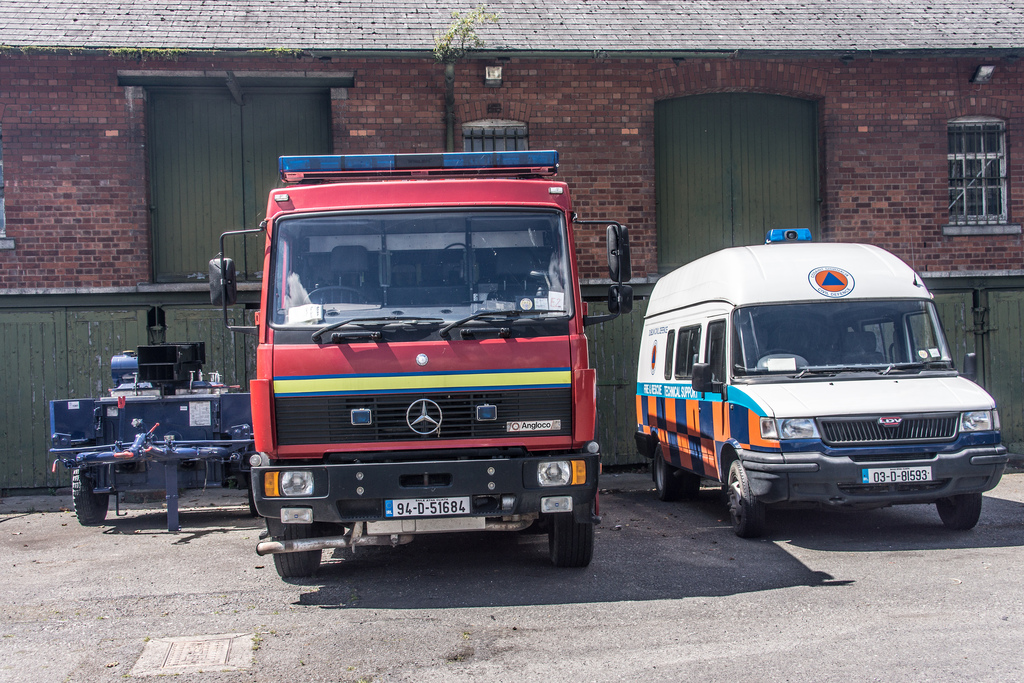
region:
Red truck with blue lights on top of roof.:
[191, 142, 635, 585]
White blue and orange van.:
[626, 222, 1006, 529]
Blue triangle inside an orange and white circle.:
[806, 259, 857, 299]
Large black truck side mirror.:
[201, 249, 243, 311]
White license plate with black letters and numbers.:
[380, 493, 475, 525]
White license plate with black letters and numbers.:
[855, 462, 935, 488]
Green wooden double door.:
[137, 76, 338, 293]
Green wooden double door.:
[650, 89, 827, 280]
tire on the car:
[267, 552, 313, 576]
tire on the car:
[550, 522, 612, 571]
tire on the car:
[933, 470, 975, 532]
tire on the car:
[640, 451, 676, 493]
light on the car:
[288, 464, 328, 513]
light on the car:
[525, 448, 579, 494]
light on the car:
[770, 418, 822, 442]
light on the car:
[551, 458, 574, 526]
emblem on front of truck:
[397, 390, 447, 442]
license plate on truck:
[376, 488, 487, 524]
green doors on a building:
[626, 74, 878, 274]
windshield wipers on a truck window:
[311, 296, 559, 353]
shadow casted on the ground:
[605, 463, 702, 609]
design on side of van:
[632, 373, 768, 491]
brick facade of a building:
[849, 73, 926, 239]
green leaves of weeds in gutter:
[429, 8, 503, 58]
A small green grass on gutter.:
[430, 12, 501, 66]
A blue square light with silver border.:
[348, 407, 374, 426]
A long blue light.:
[275, 149, 561, 169]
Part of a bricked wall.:
[849, 162, 929, 238]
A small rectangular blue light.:
[768, 227, 814, 244]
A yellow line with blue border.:
[269, 363, 579, 399]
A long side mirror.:
[604, 221, 631, 280]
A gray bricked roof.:
[0, 0, 1022, 49]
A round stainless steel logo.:
[403, 396, 446, 435]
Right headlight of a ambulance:
[952, 405, 1001, 438]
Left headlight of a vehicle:
[253, 463, 321, 508]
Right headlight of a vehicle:
[523, 452, 590, 495]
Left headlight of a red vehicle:
[256, 465, 318, 504]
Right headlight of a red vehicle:
[531, 452, 590, 492]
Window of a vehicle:
[269, 209, 563, 333]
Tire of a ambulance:
[718, 453, 770, 537]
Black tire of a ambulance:
[719, 450, 767, 542]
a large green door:
[649, 92, 830, 258]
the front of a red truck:
[253, 130, 609, 568]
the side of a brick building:
[817, 50, 950, 267]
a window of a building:
[945, 119, 1013, 227]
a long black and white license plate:
[383, 497, 483, 513]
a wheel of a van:
[716, 454, 768, 537]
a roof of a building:
[1, 0, 1020, 48]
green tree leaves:
[430, 3, 504, 60]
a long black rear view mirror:
[204, 252, 236, 311]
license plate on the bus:
[373, 490, 497, 539]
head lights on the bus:
[262, 462, 589, 513]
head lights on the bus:
[755, 402, 996, 440]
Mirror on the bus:
[205, 221, 260, 323]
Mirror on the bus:
[581, 205, 639, 317]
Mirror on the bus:
[678, 351, 730, 399]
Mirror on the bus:
[947, 332, 986, 389]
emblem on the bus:
[400, 392, 454, 443]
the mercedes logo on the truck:
[402, 396, 444, 434]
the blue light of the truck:
[349, 408, 373, 425]